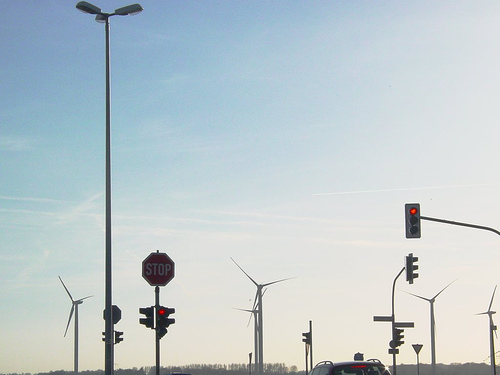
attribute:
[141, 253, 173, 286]
sign — red, white, white lettered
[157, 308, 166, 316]
light — red, overhead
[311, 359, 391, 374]
car — driving, tan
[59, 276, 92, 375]
wind mill — white, background, standing up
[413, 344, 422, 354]
sign — distant, triangle, triangular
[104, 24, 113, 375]
pole — tall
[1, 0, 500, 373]
sky — clear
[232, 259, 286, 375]
wind mill — in row